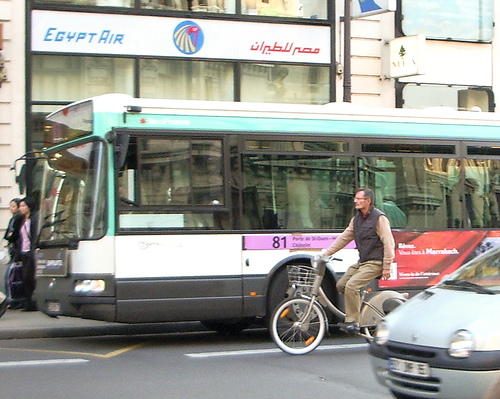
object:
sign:
[29, 10, 332, 68]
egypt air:
[42, 26, 123, 45]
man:
[318, 187, 395, 332]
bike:
[271, 258, 410, 356]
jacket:
[323, 208, 395, 269]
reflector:
[281, 309, 291, 319]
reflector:
[304, 336, 314, 345]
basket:
[286, 265, 318, 287]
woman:
[18, 200, 40, 311]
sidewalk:
[1, 308, 212, 337]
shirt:
[21, 221, 30, 253]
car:
[367, 242, 500, 399]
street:
[2, 330, 379, 398]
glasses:
[354, 196, 368, 200]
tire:
[271, 297, 328, 356]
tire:
[360, 288, 407, 345]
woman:
[4, 198, 25, 307]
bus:
[12, 94, 499, 336]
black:
[8, 243, 21, 267]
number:
[270, 237, 287, 250]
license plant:
[388, 358, 430, 376]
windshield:
[36, 141, 108, 240]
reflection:
[418, 156, 499, 224]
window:
[244, 140, 355, 229]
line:
[0, 356, 87, 366]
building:
[0, 0, 500, 235]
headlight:
[73, 278, 106, 294]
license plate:
[46, 301, 63, 314]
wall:
[340, 15, 387, 109]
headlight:
[449, 336, 469, 359]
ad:
[243, 229, 498, 293]